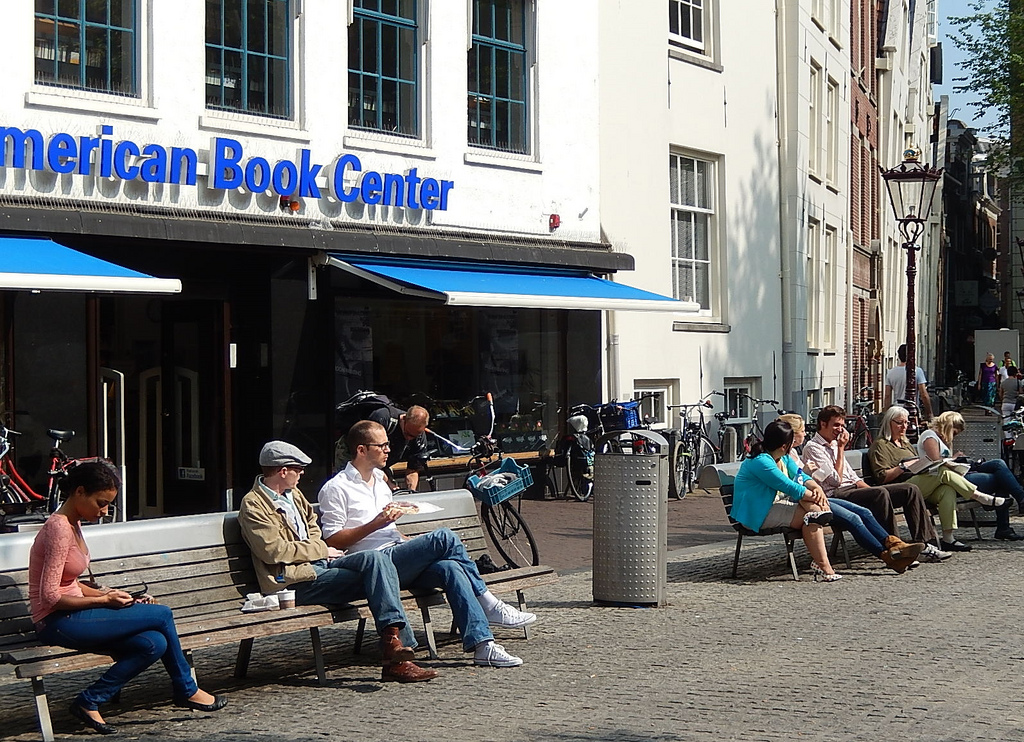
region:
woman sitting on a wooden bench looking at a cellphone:
[23, 458, 233, 740]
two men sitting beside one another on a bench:
[231, 413, 538, 688]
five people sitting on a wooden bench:
[725, 397, 1019, 584]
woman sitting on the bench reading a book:
[863, 402, 1013, 555]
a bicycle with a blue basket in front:
[424, 394, 546, 568]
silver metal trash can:
[588, 421, 675, 611]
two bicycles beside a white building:
[661, 243, 778, 503]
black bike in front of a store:
[450, 249, 701, 502]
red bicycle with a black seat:
[1, 421, 79, 519]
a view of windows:
[411, 31, 549, 134]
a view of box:
[543, 424, 718, 660]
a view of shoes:
[454, 606, 549, 687]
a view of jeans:
[392, 515, 506, 598]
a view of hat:
[221, 389, 333, 506]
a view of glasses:
[628, 105, 794, 420]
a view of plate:
[372, 471, 465, 529]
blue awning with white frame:
[310, 256, 704, 315]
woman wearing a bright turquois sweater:
[736, 450, 812, 536]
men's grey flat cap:
[250, 430, 309, 475]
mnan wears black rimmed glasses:
[340, 415, 399, 466]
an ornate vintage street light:
[878, 137, 942, 417]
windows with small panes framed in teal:
[467, 12, 534, 152]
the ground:
[768, 627, 880, 703]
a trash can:
[591, 443, 678, 618]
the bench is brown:
[175, 564, 229, 621]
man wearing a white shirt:
[333, 484, 379, 533]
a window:
[680, 172, 722, 325]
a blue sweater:
[733, 463, 771, 518]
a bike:
[462, 433, 567, 563]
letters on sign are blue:
[0, 117, 459, 213]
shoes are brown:
[377, 629, 435, 680]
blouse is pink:
[20, 507, 90, 616]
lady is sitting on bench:
[27, 460, 224, 730]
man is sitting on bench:
[239, 425, 435, 689]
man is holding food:
[314, 413, 534, 666]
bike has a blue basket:
[419, 389, 538, 568]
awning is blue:
[334, 251, 698, 312]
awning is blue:
[0, 236, 182, 291]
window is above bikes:
[669, 142, 727, 330]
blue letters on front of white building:
[3, 119, 466, 215]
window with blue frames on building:
[458, 3, 536, 156]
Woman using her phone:
[25, 472, 203, 735]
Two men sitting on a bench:
[228, 428, 520, 675]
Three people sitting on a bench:
[33, 416, 509, 692]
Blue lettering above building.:
[9, 115, 459, 224]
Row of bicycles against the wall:
[447, 384, 760, 509]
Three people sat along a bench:
[33, 416, 537, 696]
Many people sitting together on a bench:
[737, 387, 1012, 550]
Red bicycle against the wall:
[7, 423, 115, 529]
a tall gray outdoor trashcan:
[589, 424, 684, 614]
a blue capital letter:
[213, 127, 243, 191]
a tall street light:
[880, 143, 931, 431]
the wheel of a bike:
[469, 500, 540, 567]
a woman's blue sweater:
[728, 454, 811, 534]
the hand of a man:
[833, 426, 852, 453]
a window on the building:
[485, 19, 566, 171]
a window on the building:
[204, 6, 271, 99]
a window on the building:
[652, 199, 792, 447]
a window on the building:
[646, 3, 739, 114]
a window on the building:
[784, 237, 848, 371]